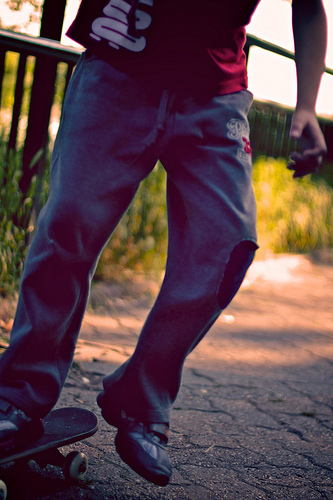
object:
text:
[89, 17, 146, 53]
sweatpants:
[0, 45, 260, 427]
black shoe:
[96, 385, 175, 487]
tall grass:
[1, 129, 20, 299]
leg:
[96, 92, 259, 490]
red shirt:
[63, 0, 261, 93]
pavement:
[0, 249, 333, 499]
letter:
[103, 1, 151, 31]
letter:
[137, 0, 153, 8]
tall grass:
[24, 142, 53, 237]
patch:
[215, 237, 258, 310]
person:
[0, 0, 326, 488]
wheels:
[63, 450, 90, 484]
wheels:
[1, 473, 11, 499]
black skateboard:
[0, 406, 99, 499]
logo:
[87, 0, 157, 51]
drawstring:
[143, 85, 180, 145]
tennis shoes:
[0, 372, 47, 462]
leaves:
[9, 0, 38, 32]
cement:
[0, 247, 331, 496]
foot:
[95, 377, 173, 488]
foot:
[0, 392, 42, 454]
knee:
[213, 223, 263, 282]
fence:
[0, 30, 332, 251]